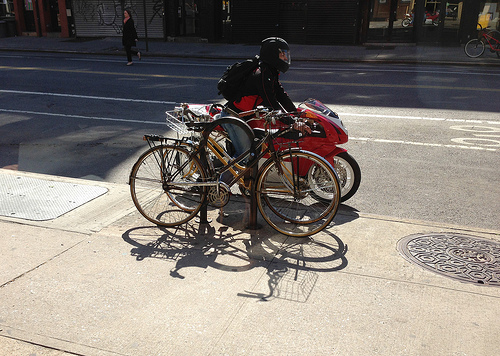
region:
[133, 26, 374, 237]
a bike is running on the road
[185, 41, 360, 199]
red color bike with the person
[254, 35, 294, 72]
a person wearing black color helmet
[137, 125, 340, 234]
cycle parked in the road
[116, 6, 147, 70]
a woman walking on the road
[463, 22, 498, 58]
a cycle parked in the side walk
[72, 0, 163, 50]
a shutter of the shop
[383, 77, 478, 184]
road marked with white color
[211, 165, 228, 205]
pedal of the cycle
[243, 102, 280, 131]
handle bar of the cycle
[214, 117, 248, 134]
a curve metal pole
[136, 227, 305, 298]
shadow on the sidewalk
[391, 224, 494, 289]
a metal manhole cover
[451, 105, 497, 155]
white letters in the street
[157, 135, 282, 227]
a black bike chained to the U pole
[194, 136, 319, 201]
a yellow bike chained to a U pole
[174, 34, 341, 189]
a person riding a red motorcycle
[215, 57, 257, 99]
a heavy black backpack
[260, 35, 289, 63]
a black helmet with a visor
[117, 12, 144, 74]
a woman crossing the street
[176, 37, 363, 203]
person riding a motorcycle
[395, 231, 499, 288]
manhole on the sidewalk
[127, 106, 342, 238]
two bicycles parked on sidewalk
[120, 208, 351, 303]
bicycles' shadows on the ground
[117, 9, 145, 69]
woman walking on the street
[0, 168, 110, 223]
manhole on the sidewalk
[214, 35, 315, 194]
person wearing backpack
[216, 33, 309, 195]
person wearing black helmet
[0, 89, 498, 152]
white lines painted on the street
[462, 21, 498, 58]
front tire of bicycle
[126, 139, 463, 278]
This is a bike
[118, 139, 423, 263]
This is a picture of wheels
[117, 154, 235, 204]
The wheels are large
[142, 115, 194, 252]
These are metal spikes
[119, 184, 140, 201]
The tire is made of rubber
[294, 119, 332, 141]
This is a motorcycle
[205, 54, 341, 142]
This is a backpack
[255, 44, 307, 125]
The helmet is black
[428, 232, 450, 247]
This is a pothole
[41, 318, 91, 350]
This is a sidewalk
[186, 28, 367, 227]
person on a motor cycle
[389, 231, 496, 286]
circular manhole cover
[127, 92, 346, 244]
bicycle rack with parked bikes.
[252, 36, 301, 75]
black helmet on a motorcyclist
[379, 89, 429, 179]
white lines on a city street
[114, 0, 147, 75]
woman crossing the street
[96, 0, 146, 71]
pedestrian in the road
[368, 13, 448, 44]
storefront across the street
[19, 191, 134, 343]
sidewalk in the city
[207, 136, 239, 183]
yellow bicycle body